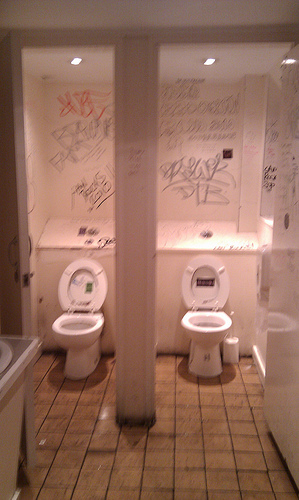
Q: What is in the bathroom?
A: Two toilets.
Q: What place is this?
A: Bathroom.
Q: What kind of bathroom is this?
A: Public.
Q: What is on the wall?
A: Graffiti.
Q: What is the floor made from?
A: Tiles.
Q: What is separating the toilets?
A: Wall.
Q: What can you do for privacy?
A: Close door.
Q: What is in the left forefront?
A: Sink.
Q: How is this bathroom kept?
A: Dirty.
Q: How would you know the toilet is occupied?
A: Door is closed.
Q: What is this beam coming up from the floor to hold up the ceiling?
A: Support beam.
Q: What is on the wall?
A: Graffiti.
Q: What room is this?
A: Bathroom.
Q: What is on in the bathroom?
A: Lights.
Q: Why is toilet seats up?
A: Cleaned.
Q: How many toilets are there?
A: Two.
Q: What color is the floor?
A: Brown.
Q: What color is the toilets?
A: White.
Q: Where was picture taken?
A: In a bathroom.